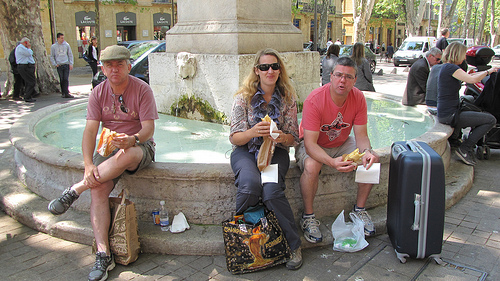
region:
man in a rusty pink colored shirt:
[42, 42, 164, 276]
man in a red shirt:
[297, 57, 388, 247]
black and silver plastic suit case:
[381, 128, 461, 274]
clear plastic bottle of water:
[152, 197, 170, 233]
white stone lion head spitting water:
[165, 47, 202, 84]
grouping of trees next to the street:
[307, 1, 499, 50]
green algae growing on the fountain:
[164, 91, 228, 127]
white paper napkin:
[354, 156, 382, 189]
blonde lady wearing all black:
[436, 36, 495, 163]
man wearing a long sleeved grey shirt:
[42, 26, 82, 97]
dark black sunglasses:
[257, 62, 280, 70]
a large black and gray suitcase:
[387, 137, 448, 263]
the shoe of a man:
[299, 212, 321, 243]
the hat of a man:
[92, 42, 132, 62]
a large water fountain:
[0, 80, 477, 255]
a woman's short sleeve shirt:
[436, 62, 466, 114]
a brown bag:
[103, 184, 140, 269]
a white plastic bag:
[332, 207, 372, 250]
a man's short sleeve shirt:
[300, 83, 367, 149]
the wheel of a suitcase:
[434, 255, 445, 262]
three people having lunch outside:
[39, 40, 376, 280]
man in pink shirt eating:
[41, 42, 160, 279]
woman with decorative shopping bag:
[223, 47, 306, 276]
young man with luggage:
[298, 57, 444, 265]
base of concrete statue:
[1, 98, 481, 254]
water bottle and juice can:
[151, 198, 173, 232]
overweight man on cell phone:
[13, 37, 36, 100]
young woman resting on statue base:
[436, 42, 496, 165]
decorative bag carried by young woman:
[222, 212, 293, 277]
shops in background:
[311, 0, 428, 54]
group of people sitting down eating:
[35, 17, 449, 241]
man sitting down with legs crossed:
[55, 41, 169, 242]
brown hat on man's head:
[98, 35, 132, 76]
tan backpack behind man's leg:
[68, 192, 158, 279]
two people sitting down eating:
[191, 45, 393, 256]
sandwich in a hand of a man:
[335, 144, 375, 184]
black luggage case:
[370, 125, 451, 266]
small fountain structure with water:
[47, 8, 419, 189]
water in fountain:
[168, 125, 222, 163]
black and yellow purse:
[181, 200, 309, 277]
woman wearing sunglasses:
[228, 47, 303, 277]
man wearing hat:
[47, 44, 161, 280]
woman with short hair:
[434, 39, 496, 165]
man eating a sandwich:
[295, 56, 381, 244]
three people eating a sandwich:
[46, 45, 381, 280]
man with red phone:
[13, 36, 38, 103]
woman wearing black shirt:
[435, 41, 497, 167]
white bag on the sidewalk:
[329, 209, 369, 254]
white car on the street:
[392, 36, 437, 67]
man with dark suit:
[401, 44, 441, 106]